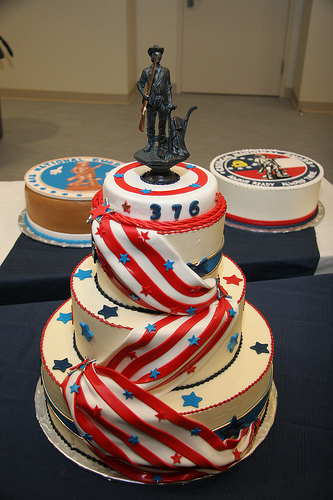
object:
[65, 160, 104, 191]
smiling woman